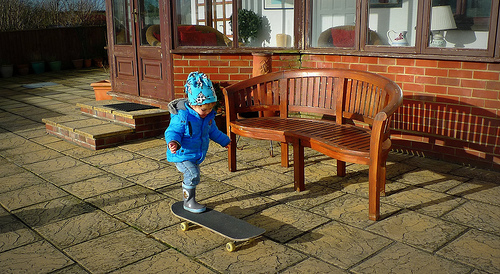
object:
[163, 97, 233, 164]
jacket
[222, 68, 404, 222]
bench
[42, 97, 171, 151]
steps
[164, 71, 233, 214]
boy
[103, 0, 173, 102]
door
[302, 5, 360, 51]
windows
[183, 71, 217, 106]
hat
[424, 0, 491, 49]
glass pane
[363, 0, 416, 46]
glass pane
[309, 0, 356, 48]
glass pane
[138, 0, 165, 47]
glass pane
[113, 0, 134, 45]
glass pane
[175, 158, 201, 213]
pants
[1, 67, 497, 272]
ground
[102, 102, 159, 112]
mat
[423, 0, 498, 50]
window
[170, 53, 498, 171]
wall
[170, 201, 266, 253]
skate board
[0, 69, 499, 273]
tiled ground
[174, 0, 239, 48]
windows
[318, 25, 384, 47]
chair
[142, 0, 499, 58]
room